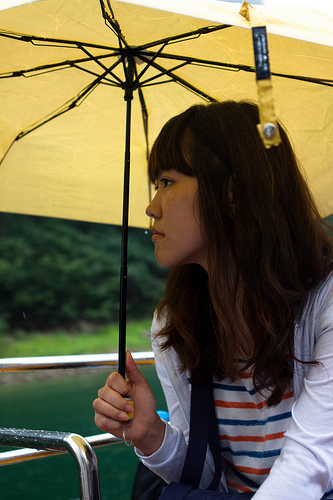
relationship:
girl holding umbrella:
[93, 98, 331, 491] [2, 1, 331, 232]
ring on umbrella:
[118, 424, 135, 447] [2, 1, 331, 232]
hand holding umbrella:
[92, 349, 158, 446] [2, 1, 331, 232]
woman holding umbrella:
[93, 98, 331, 491] [2, 1, 331, 232]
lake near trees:
[0, 366, 170, 499] [1, 215, 165, 336]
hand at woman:
[92, 349, 158, 446] [93, 98, 331, 491]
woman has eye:
[93, 98, 331, 491] [158, 177, 175, 189]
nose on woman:
[145, 193, 162, 220] [93, 98, 331, 491]